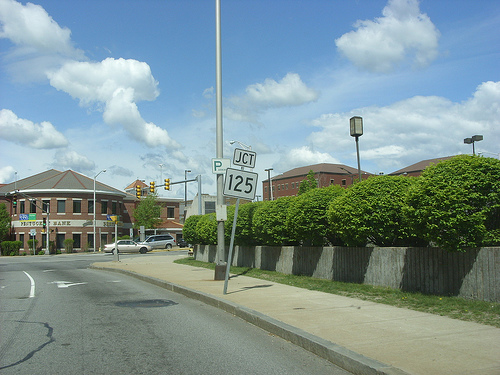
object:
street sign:
[217, 146, 261, 297]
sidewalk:
[102, 257, 499, 374]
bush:
[405, 154, 499, 249]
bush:
[324, 175, 411, 247]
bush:
[282, 184, 341, 241]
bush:
[248, 194, 297, 247]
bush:
[195, 213, 217, 246]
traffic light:
[133, 181, 144, 203]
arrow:
[48, 277, 88, 290]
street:
[3, 255, 382, 372]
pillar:
[222, 197, 241, 294]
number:
[221, 166, 259, 201]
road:
[1, 252, 357, 374]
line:
[19, 267, 39, 301]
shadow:
[230, 283, 272, 297]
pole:
[223, 199, 242, 296]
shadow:
[231, 265, 252, 278]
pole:
[211, 2, 231, 280]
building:
[0, 168, 183, 256]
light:
[348, 114, 367, 182]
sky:
[2, 2, 494, 145]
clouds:
[0, 109, 43, 145]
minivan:
[141, 233, 177, 250]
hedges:
[400, 156, 500, 250]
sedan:
[101, 239, 154, 255]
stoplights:
[148, 181, 156, 194]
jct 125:
[221, 147, 263, 200]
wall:
[195, 249, 500, 301]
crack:
[0, 316, 58, 370]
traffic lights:
[162, 179, 172, 191]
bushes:
[184, 213, 206, 242]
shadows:
[401, 246, 480, 294]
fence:
[289, 242, 499, 300]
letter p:
[212, 157, 224, 174]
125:
[227, 172, 255, 192]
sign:
[224, 166, 259, 200]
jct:
[235, 150, 257, 167]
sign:
[233, 147, 258, 168]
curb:
[92, 264, 293, 336]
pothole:
[115, 295, 179, 311]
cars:
[103, 239, 158, 254]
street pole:
[216, 199, 242, 298]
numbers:
[243, 176, 252, 193]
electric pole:
[209, 0, 229, 280]